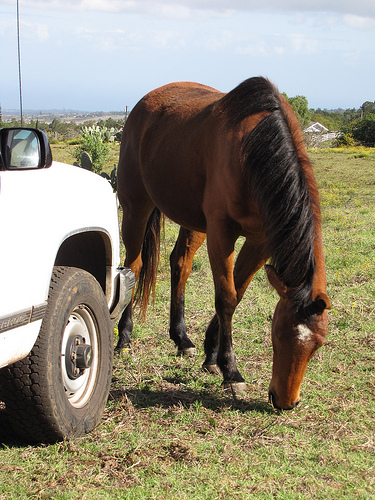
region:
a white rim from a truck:
[62, 306, 98, 407]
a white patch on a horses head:
[294, 320, 310, 342]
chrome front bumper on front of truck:
[115, 268, 134, 324]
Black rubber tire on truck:
[2, 263, 114, 437]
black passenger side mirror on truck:
[2, 124, 52, 172]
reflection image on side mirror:
[6, 134, 40, 169]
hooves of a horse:
[116, 338, 246, 391]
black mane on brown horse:
[222, 75, 315, 326]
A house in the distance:
[300, 116, 342, 147]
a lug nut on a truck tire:
[65, 349, 77, 359]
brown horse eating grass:
[119, 58, 331, 454]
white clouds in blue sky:
[18, 29, 54, 76]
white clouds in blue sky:
[44, 29, 79, 55]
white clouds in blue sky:
[294, 6, 364, 58]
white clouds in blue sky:
[295, 9, 362, 100]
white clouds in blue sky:
[210, 12, 255, 68]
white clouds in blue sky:
[168, 10, 216, 46]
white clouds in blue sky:
[64, 24, 106, 72]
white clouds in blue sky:
[41, 13, 94, 75]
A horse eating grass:
[102, 69, 339, 416]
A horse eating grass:
[111, 71, 334, 415]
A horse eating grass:
[107, 72, 334, 411]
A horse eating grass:
[109, 73, 334, 423]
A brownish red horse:
[106, 62, 356, 411]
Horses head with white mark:
[261, 280, 330, 425]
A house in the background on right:
[300, 107, 349, 152]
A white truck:
[2, 120, 137, 435]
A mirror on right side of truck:
[0, 116, 49, 171]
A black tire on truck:
[30, 256, 114, 436]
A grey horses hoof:
[214, 371, 255, 414]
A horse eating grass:
[119, 72, 341, 481]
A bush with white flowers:
[79, 124, 115, 159]